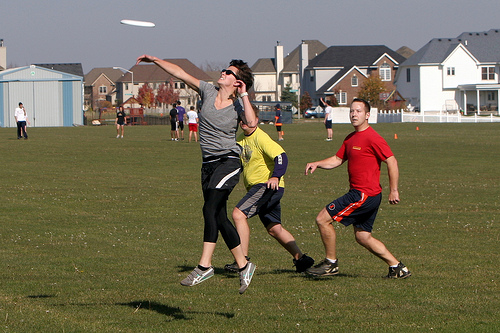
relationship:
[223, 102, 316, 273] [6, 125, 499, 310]
people on field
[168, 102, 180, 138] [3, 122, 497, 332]
person on field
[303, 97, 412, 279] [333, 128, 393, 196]
man wearing red shirt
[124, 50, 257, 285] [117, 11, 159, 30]
lady reaching for frisbee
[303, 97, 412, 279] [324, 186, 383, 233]
man wearing shorts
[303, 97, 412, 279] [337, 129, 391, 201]
man wearing shirt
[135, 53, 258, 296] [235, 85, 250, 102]
lady wearing bracelet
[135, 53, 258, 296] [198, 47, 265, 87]
lady wearing glasses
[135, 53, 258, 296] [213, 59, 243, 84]
lady wearing glasses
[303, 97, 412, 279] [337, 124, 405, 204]
man has shirt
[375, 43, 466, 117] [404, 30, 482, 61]
house has roof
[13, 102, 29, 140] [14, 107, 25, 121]
person wearing shirt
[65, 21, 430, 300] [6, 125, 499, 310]
people playing field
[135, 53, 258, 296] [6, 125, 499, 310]
lady on field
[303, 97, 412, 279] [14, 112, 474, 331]
man on field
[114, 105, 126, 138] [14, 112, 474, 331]
person on field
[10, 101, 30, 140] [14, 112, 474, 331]
person on field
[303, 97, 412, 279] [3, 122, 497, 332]
man on field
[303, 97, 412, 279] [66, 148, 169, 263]
man on field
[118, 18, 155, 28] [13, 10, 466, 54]
fridbie in air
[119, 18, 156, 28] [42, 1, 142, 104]
fridbie in air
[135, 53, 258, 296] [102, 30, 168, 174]
lady in air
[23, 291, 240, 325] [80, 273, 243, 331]
shadow on ground